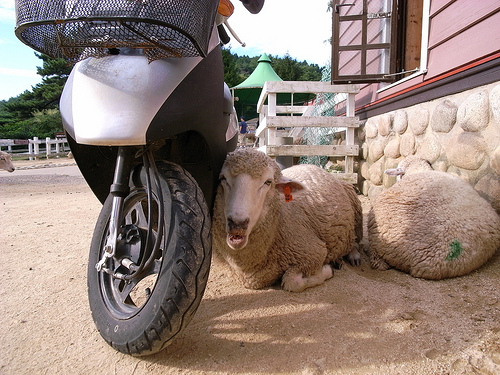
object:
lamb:
[222, 144, 365, 291]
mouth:
[225, 232, 248, 245]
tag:
[268, 192, 307, 207]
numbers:
[282, 185, 287, 202]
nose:
[232, 211, 250, 239]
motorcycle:
[16, 6, 288, 364]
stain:
[445, 241, 462, 258]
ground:
[218, 299, 470, 357]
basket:
[15, 2, 220, 65]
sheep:
[366, 159, 495, 277]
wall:
[322, 72, 495, 207]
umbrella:
[230, 51, 317, 94]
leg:
[282, 254, 335, 289]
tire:
[85, 159, 212, 348]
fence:
[260, 79, 360, 193]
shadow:
[160, 303, 470, 373]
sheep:
[1, 150, 17, 175]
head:
[0, 151, 15, 173]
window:
[329, 1, 401, 80]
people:
[236, 114, 247, 144]